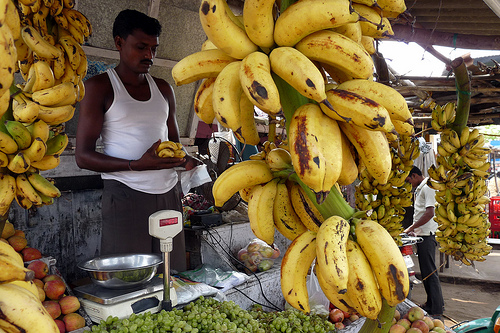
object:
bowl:
[78, 251, 165, 291]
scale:
[76, 210, 185, 323]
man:
[75, 11, 208, 277]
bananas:
[158, 146, 177, 159]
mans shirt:
[98, 69, 188, 197]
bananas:
[353, 220, 412, 308]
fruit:
[449, 129, 464, 146]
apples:
[405, 307, 429, 322]